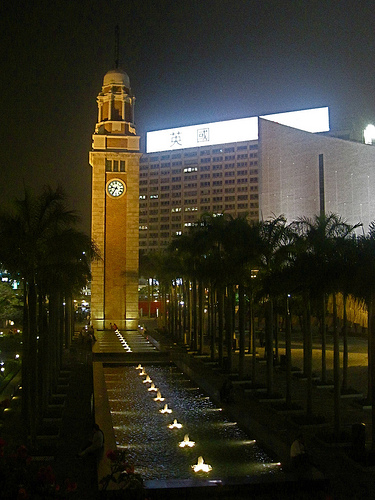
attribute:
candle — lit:
[140, 376, 153, 382]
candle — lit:
[178, 433, 194, 446]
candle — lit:
[165, 414, 183, 427]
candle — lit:
[190, 455, 210, 468]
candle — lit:
[178, 435, 192, 453]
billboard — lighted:
[139, 111, 353, 159]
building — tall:
[76, 57, 171, 329]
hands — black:
[109, 185, 118, 195]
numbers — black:
[108, 180, 124, 195]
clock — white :
[106, 177, 127, 199]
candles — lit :
[108, 328, 216, 475]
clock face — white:
[105, 178, 124, 198]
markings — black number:
[108, 181, 120, 193]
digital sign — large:
[144, 106, 330, 154]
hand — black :
[110, 186, 118, 197]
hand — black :
[110, 184, 116, 189]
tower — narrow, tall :
[78, 61, 150, 329]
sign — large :
[146, 98, 331, 160]